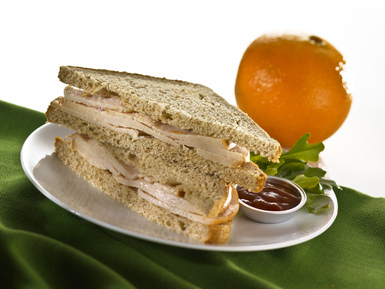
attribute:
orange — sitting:
[264, 30, 346, 139]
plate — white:
[276, 228, 302, 250]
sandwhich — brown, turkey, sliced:
[69, 62, 228, 225]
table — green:
[25, 216, 92, 259]